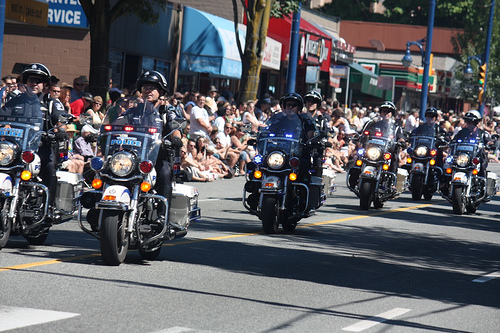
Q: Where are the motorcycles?
A: In the street.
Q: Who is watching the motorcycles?
A: Spectators.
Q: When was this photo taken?
A: During the day.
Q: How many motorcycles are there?
A: Six.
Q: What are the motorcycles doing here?
A: It's a parade.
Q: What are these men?
A: Policemen.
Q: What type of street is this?
A: A city street.